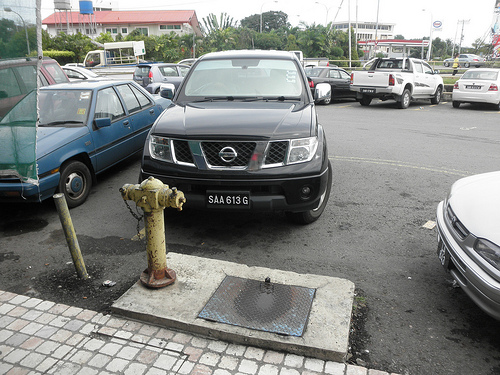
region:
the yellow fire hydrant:
[118, 176, 190, 293]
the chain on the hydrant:
[122, 193, 149, 240]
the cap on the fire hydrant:
[169, 188, 184, 209]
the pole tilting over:
[52, 189, 94, 284]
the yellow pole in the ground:
[51, 192, 94, 284]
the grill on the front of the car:
[171, 134, 287, 172]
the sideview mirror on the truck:
[313, 82, 330, 102]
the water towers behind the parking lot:
[52, 0, 102, 40]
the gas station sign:
[426, 16, 448, 66]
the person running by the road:
[451, 49, 463, 82]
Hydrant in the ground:
[117, 173, 187, 293]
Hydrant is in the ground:
[119, 174, 192, 289]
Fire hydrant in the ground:
[118, 172, 189, 290]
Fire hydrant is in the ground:
[112, 174, 193, 291]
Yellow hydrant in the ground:
[117, 171, 185, 291]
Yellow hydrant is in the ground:
[113, 172, 190, 300]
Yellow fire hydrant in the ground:
[115, 174, 188, 293]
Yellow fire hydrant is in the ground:
[119, 175, 189, 293]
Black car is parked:
[132, 42, 342, 225]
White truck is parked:
[342, 55, 446, 108]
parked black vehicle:
[138, 47, 334, 224]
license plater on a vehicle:
[203, 193, 251, 205]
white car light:
[288, 138, 322, 165]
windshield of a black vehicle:
[181, 55, 308, 106]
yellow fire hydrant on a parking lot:
[115, 173, 190, 290]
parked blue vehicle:
[0, 75, 164, 215]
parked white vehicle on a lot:
[345, 54, 447, 110]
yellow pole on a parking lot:
[48, 189, 98, 279]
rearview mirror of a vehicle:
[310, 79, 333, 107]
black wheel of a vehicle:
[55, 158, 97, 208]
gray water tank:
[51, 0, 73, 43]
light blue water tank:
[76, 0, 96, 41]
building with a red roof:
[41, 10, 201, 46]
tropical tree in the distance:
[195, 10, 242, 57]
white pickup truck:
[348, 56, 445, 106]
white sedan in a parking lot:
[449, 68, 498, 108]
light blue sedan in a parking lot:
[1, 80, 173, 208]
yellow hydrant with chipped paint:
[116, 176, 186, 289]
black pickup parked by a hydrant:
[139, 48, 333, 225]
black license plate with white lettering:
[204, 189, 252, 210]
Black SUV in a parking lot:
[141, 14, 361, 229]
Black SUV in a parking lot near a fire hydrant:
[124, 39, 354, 341]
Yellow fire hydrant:
[113, 174, 193, 298]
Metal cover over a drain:
[192, 242, 323, 356]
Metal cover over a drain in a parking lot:
[196, 177, 377, 369]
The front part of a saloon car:
[393, 153, 496, 332]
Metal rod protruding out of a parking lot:
[36, 186, 96, 293]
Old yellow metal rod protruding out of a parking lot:
[46, 190, 93, 281]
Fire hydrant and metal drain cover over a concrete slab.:
[112, 170, 368, 361]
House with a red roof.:
[42, 7, 213, 41]